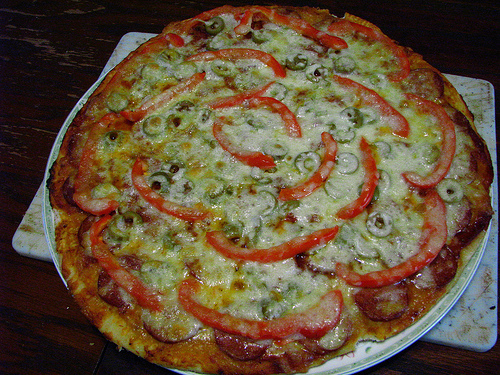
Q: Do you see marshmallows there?
A: No, there are no marshmallows.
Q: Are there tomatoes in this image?
A: Yes, there is a tomato.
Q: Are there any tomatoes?
A: Yes, there is a tomato.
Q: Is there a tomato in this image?
A: Yes, there is a tomato.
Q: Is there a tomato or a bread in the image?
A: Yes, there is a tomato.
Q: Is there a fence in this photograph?
A: No, there are no fences.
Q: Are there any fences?
A: No, there are no fences.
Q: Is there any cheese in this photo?
A: Yes, there is cheese.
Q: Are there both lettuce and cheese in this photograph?
A: No, there is cheese but no lettuce.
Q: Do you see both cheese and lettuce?
A: No, there is cheese but no lettuce.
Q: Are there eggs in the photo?
A: No, there are no eggs.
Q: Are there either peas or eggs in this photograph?
A: No, there are no eggs or peas.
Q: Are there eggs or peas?
A: No, there are no eggs or peas.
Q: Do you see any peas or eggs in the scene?
A: No, there are no eggs or peas.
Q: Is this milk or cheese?
A: This is cheese.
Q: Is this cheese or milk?
A: This is cheese.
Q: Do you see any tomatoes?
A: Yes, there is a tomato.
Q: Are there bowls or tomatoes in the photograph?
A: Yes, there is a tomato.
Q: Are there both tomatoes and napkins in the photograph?
A: No, there is a tomato but no napkins.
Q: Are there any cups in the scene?
A: No, there are no cups.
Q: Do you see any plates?
A: Yes, there is a plate.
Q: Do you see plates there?
A: Yes, there is a plate.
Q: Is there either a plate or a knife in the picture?
A: Yes, there is a plate.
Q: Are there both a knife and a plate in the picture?
A: No, there is a plate but no knives.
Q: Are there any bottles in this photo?
A: No, there are no bottles.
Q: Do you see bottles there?
A: No, there are no bottles.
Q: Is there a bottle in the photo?
A: No, there are no bottles.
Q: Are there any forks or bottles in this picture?
A: No, there are no bottles or forks.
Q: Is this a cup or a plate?
A: This is a plate.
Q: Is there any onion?
A: No, there are no onions.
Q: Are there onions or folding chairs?
A: No, there are no onions or folding chairs.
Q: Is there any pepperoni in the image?
A: Yes, there is pepperoni.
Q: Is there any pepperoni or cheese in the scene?
A: Yes, there is pepperoni.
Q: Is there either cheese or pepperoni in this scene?
A: Yes, there is pepperoni.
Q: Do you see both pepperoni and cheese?
A: Yes, there are both pepperoni and cheese.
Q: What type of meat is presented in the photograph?
A: The meat is pepperoni.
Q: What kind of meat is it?
A: The meat is pepperoni.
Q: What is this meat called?
A: This is pepperoni.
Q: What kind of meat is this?
A: This is pepperoni.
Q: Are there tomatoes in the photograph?
A: Yes, there is a tomato.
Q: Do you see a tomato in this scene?
A: Yes, there is a tomato.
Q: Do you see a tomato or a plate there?
A: Yes, there is a tomato.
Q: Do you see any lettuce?
A: No, there is no lettuce.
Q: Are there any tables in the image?
A: Yes, there is a table.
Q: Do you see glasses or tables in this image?
A: Yes, there is a table.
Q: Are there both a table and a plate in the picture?
A: Yes, there are both a table and a plate.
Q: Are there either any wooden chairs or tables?
A: Yes, there is a wood table.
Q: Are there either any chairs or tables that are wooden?
A: Yes, the table is wooden.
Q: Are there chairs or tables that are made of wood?
A: Yes, the table is made of wood.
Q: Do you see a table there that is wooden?
A: Yes, there is a wood table.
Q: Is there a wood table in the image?
A: Yes, there is a wood table.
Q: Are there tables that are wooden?
A: Yes, there is a table that is wooden.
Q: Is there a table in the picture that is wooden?
A: Yes, there is a table that is wooden.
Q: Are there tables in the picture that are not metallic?
A: Yes, there is a wooden table.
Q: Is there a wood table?
A: Yes, there is a table that is made of wood.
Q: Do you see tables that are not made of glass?
A: Yes, there is a table that is made of wood.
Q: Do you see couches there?
A: No, there are no couches.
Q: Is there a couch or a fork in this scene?
A: No, there are no couches or forks.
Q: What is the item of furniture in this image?
A: The piece of furniture is a table.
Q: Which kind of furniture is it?
A: The piece of furniture is a table.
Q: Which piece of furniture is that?
A: This is a table.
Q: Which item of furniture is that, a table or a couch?
A: This is a table.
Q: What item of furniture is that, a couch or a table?
A: This is a table.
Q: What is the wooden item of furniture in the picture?
A: The piece of furniture is a table.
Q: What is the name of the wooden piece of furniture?
A: The piece of furniture is a table.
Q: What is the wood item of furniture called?
A: The piece of furniture is a table.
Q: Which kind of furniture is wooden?
A: The furniture is a table.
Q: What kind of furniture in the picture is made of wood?
A: The furniture is a table.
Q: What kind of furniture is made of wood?
A: The furniture is a table.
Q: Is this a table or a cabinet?
A: This is a table.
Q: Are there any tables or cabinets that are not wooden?
A: No, there is a table but it is wooden.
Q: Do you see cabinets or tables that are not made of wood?
A: No, there is a table but it is made of wood.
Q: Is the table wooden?
A: Yes, the table is wooden.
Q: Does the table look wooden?
A: Yes, the table is wooden.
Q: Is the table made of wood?
A: Yes, the table is made of wood.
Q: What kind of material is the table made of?
A: The table is made of wood.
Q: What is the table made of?
A: The table is made of wood.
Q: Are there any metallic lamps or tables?
A: No, there is a table but it is wooden.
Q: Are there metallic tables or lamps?
A: No, there is a table but it is wooden.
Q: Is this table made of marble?
A: No, the table is made of wood.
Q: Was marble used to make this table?
A: No, the table is made of wood.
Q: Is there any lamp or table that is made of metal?
A: No, there is a table but it is made of wood.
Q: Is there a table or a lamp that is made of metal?
A: No, there is a table but it is made of wood.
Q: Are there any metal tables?
A: No, there is a table but it is made of wood.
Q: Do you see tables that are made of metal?
A: No, there is a table but it is made of wood.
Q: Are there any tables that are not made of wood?
A: No, there is a table but it is made of wood.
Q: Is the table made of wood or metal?
A: The table is made of wood.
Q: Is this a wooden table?
A: Yes, this is a wooden table.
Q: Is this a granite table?
A: No, this is a wooden table.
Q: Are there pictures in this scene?
A: No, there are no pictures.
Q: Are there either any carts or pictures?
A: No, there are no pictures or carts.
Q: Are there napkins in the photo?
A: No, there are no napkins.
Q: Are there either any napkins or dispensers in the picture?
A: No, there are no napkins or dispensers.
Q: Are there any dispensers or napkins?
A: No, there are no napkins or dispensers.